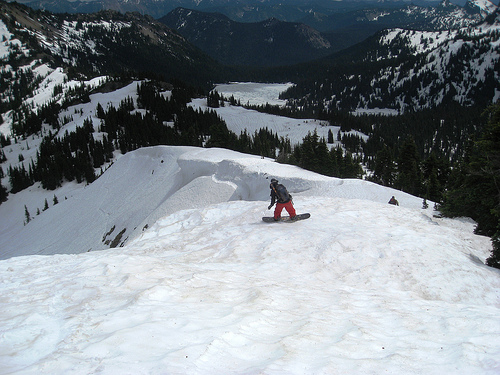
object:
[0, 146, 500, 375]
snow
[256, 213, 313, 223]
snowboard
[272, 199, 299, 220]
pants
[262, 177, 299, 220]
skier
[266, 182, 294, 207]
coat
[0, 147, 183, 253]
slope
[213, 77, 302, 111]
white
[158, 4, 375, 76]
mountain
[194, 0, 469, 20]
distance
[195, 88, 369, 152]
valley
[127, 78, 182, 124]
line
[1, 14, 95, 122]
trees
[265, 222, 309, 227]
shadow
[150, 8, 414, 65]
background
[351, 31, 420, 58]
group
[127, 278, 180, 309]
trail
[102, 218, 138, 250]
rocks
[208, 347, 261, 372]
collapsed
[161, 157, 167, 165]
grass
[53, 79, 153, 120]
snowy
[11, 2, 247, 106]
mountainside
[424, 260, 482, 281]
streaks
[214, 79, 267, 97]
ice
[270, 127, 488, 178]
evergreen